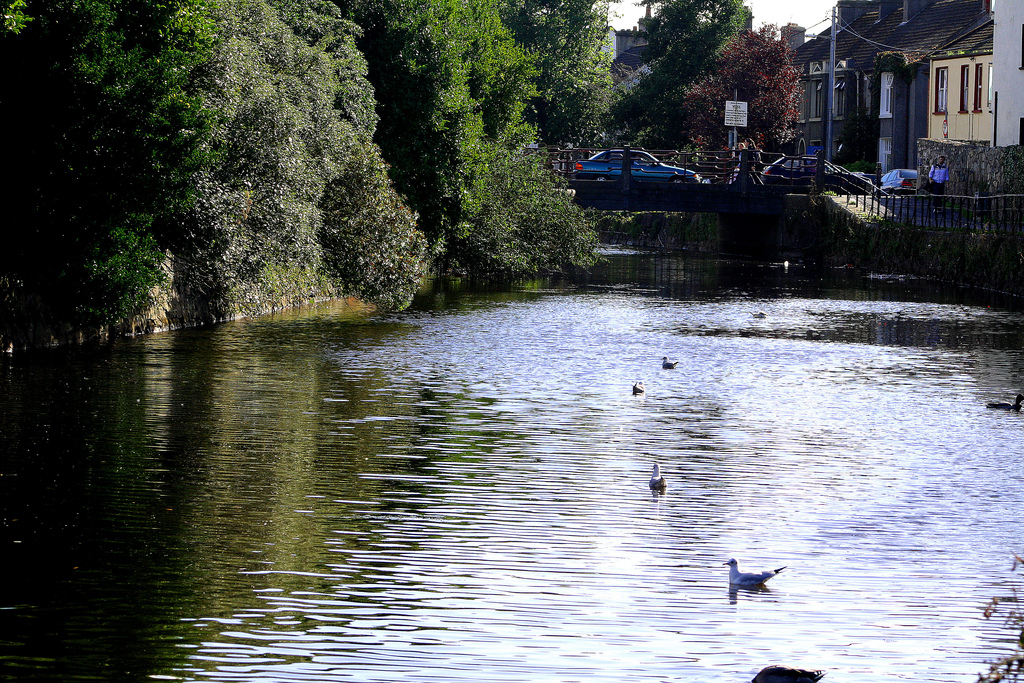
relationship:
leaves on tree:
[93, 45, 362, 299] [78, 62, 288, 281]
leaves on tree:
[385, 97, 660, 295] [385, 97, 660, 295]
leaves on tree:
[472, 198, 595, 280] [353, 138, 630, 357]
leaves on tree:
[365, 2, 524, 225] [382, 27, 610, 190]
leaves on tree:
[194, 0, 365, 300] [268, 85, 487, 202]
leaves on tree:
[0, 0, 199, 316] [96, 147, 309, 217]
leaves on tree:
[0, 0, 199, 316] [90, 59, 332, 196]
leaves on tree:
[0, 0, 199, 316] [81, 68, 244, 202]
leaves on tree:
[166, 47, 356, 228] [166, 47, 356, 228]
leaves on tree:
[194, 0, 365, 300] [151, 83, 428, 246]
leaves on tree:
[0, 0, 199, 316] [122, 100, 318, 263]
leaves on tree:
[365, 2, 524, 225] [385, 39, 601, 220]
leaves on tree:
[472, 198, 595, 280] [455, 205, 621, 289]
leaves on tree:
[365, 2, 524, 225] [374, 27, 537, 144]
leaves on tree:
[472, 198, 595, 280] [388, 144, 595, 290]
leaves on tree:
[315, 45, 551, 249] [315, 45, 551, 249]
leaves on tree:
[194, 0, 365, 300] [221, 208, 487, 351]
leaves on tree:
[194, 0, 365, 300] [280, 77, 511, 243]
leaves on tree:
[0, 0, 199, 316] [99, 167, 248, 295]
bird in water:
[672, 501, 879, 673] [13, 217, 1022, 675]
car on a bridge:
[579, 147, 703, 186] [572, 172, 806, 291]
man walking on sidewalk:
[915, 150, 954, 202] [791, 198, 1021, 265]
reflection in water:
[147, 321, 389, 563] [32, 287, 1022, 674]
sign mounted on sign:
[713, 96, 761, 139] [725, 100, 748, 126]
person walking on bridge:
[744, 138, 763, 184] [547, 175, 861, 262]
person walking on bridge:
[743, 139, 767, 185] [547, 175, 861, 262]